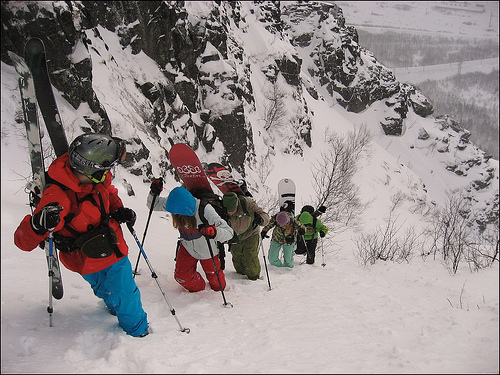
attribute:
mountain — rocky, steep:
[2, 1, 500, 375]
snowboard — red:
[166, 141, 214, 194]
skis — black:
[7, 37, 66, 298]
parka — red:
[13, 151, 128, 276]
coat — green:
[296, 211, 328, 240]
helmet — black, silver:
[67, 132, 125, 186]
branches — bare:
[356, 189, 498, 275]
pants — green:
[268, 238, 295, 270]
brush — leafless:
[307, 123, 379, 264]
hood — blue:
[165, 185, 197, 216]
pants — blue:
[80, 256, 150, 337]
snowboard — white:
[278, 177, 296, 219]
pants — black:
[296, 235, 318, 266]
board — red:
[204, 161, 246, 196]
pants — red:
[172, 240, 227, 292]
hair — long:
[170, 212, 198, 232]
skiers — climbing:
[7, 36, 327, 338]